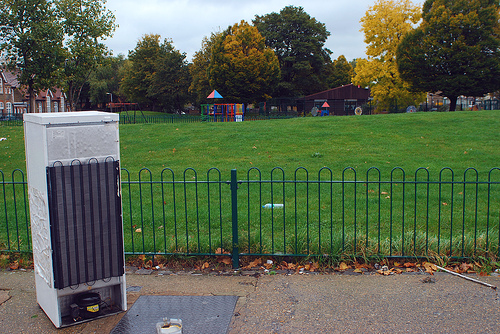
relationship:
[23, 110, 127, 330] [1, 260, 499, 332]
fridge on sidewalk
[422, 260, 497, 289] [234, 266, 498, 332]
stick on sidewalk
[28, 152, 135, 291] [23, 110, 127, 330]
coils on back of fridge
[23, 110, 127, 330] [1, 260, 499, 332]
fridge on a sidewalk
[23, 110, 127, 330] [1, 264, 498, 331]
fridge in street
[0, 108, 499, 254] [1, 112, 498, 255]
grass in field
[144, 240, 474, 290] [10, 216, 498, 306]
leaves are on ground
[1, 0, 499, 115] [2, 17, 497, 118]
trees are in background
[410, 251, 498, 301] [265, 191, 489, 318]
stick on ground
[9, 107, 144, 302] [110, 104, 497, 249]
fridge at park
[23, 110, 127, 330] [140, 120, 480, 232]
fridge at park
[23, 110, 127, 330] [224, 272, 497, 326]
fridge on sidewalk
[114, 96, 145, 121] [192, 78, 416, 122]
swing set on playground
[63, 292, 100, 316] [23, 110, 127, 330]
motor of fridge